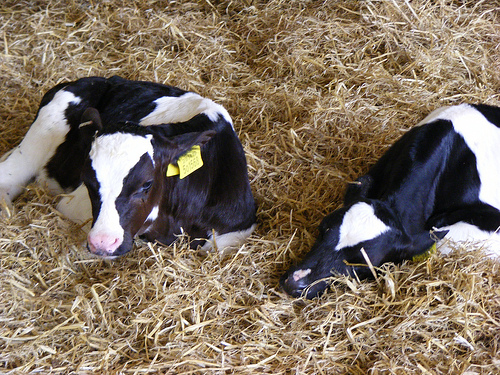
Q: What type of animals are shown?
A: Cows.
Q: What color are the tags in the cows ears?
A: Yellow.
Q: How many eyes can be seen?
A: One.